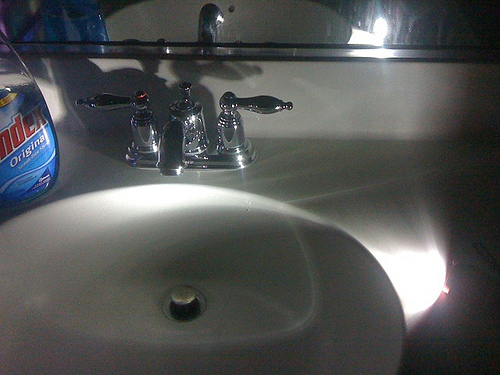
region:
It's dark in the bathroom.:
[6, 7, 488, 361]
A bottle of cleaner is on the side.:
[0, 11, 61, 207]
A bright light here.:
[399, 228, 494, 308]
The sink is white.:
[61, 182, 383, 373]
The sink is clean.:
[66, 189, 374, 367]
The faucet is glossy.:
[73, 71, 304, 203]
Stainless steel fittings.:
[64, 71, 303, 208]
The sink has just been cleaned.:
[6, 64, 493, 370]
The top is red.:
[68, 69, 171, 171]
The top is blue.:
[212, 75, 300, 175]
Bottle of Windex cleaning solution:
[0, 18, 68, 230]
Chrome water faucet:
[77, 83, 301, 193]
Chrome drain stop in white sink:
[148, 270, 217, 330]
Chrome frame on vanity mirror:
[243, 38, 475, 70]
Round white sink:
[15, 205, 400, 367]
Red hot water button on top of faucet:
[132, 85, 154, 103]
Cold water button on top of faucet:
[219, 83, 251, 117]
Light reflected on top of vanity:
[351, 220, 453, 320]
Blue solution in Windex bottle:
[26, 3, 111, 43]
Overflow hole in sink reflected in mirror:
[221, 1, 260, 38]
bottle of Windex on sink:
[0, 19, 72, 224]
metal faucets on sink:
[57, 78, 322, 185]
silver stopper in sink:
[151, 279, 226, 332]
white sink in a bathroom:
[7, 40, 487, 369]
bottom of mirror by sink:
[9, 8, 489, 65]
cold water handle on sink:
[212, 87, 302, 133]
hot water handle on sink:
[67, 84, 159, 125]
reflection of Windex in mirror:
[25, 1, 121, 51]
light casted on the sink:
[357, 225, 456, 327]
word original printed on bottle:
[4, 131, 54, 171]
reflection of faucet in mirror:
[181, 3, 243, 55]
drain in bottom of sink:
[150, 276, 212, 327]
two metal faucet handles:
[75, 74, 305, 152]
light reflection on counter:
[369, 221, 456, 327]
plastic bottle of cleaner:
[4, 82, 65, 204]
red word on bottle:
[1, 100, 48, 154]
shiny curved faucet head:
[149, 115, 205, 189]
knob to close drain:
[170, 68, 197, 120]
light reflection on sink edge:
[119, 181, 214, 217]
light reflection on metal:
[226, 141, 252, 173]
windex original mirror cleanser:
[1, 33, 61, 207]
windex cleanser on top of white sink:
[0, 26, 60, 208]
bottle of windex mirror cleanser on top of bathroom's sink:
[0, 30, 60, 206]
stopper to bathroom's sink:
[160, 285, 206, 322]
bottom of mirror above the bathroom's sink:
[0, 0, 495, 60]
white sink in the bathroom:
[0, 60, 495, 370]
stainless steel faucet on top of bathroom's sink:
[75, 80, 291, 175]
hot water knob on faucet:
[72, 85, 153, 147]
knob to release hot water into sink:
[212, 87, 292, 148]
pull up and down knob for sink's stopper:
[175, 77, 195, 105]